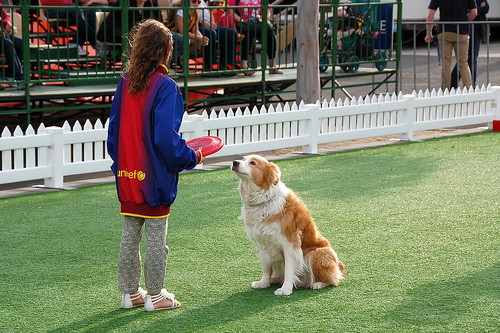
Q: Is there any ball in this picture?
A: No, there are no balls.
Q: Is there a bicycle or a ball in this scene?
A: No, there are no balls or bicycles.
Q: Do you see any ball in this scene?
A: No, there are no balls.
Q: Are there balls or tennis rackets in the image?
A: No, there are no balls or tennis rackets.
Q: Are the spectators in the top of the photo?
A: Yes, the spectators are in the top of the image.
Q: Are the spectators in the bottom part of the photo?
A: No, the spectators are in the top of the image.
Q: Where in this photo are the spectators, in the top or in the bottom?
A: The spectators are in the top of the image.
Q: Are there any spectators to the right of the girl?
A: Yes, there are spectators to the right of the girl.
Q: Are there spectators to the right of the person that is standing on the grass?
A: Yes, there are spectators to the right of the girl.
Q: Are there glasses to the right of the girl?
A: No, there are spectators to the right of the girl.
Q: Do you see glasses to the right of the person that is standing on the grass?
A: No, there are spectators to the right of the girl.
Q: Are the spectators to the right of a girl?
A: Yes, the spectators are to the right of a girl.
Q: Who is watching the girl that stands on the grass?
A: The spectators are watching the girl.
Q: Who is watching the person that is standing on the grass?
A: The spectators are watching the girl.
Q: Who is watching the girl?
A: The spectators are watching the girl.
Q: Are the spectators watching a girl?
A: Yes, the spectators are watching a girl.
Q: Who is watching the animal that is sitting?
A: The spectators are watching the dog.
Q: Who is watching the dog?
A: The spectators are watching the dog.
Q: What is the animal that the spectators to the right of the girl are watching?
A: The animal is a dog.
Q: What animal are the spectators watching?
A: The spectators are watching the dog.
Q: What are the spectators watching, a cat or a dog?
A: The spectators are watching a dog.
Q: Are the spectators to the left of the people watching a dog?
A: Yes, the spectators are watching a dog.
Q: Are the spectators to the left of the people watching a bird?
A: No, the spectators are watching a dog.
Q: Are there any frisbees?
A: Yes, there is a frisbee.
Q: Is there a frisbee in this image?
A: Yes, there is a frisbee.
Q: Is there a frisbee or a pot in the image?
A: Yes, there is a frisbee.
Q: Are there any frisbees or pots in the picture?
A: Yes, there is a frisbee.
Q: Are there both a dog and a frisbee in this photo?
A: Yes, there are both a frisbee and a dog.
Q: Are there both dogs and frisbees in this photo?
A: Yes, there are both a frisbee and a dog.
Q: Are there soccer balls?
A: No, there are no soccer balls.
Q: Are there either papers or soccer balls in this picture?
A: No, there are no soccer balls or papers.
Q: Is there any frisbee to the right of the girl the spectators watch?
A: Yes, there is a frisbee to the right of the girl.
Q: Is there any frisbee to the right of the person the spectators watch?
A: Yes, there is a frisbee to the right of the girl.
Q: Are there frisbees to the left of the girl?
A: No, the frisbee is to the right of the girl.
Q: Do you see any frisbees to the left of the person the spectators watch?
A: No, the frisbee is to the right of the girl.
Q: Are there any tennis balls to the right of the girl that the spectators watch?
A: No, there is a frisbee to the right of the girl.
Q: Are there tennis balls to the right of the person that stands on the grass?
A: No, there is a frisbee to the right of the girl.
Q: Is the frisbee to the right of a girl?
A: Yes, the frisbee is to the right of a girl.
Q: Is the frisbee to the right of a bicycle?
A: No, the frisbee is to the right of a girl.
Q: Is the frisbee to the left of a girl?
A: No, the frisbee is to the right of a girl.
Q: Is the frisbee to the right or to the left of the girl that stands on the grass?
A: The frisbee is to the right of the girl.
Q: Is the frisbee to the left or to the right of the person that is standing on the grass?
A: The frisbee is to the right of the girl.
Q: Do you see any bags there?
A: No, there are no bags.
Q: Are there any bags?
A: No, there are no bags.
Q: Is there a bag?
A: No, there are no bags.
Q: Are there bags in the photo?
A: No, there are no bags.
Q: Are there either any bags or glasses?
A: No, there are no bags or glasses.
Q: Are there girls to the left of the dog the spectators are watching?
A: Yes, there is a girl to the left of the dog.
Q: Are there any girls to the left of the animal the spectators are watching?
A: Yes, there is a girl to the left of the dog.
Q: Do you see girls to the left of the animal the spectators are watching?
A: Yes, there is a girl to the left of the dog.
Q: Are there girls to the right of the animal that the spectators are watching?
A: No, the girl is to the left of the dog.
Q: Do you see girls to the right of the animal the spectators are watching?
A: No, the girl is to the left of the dog.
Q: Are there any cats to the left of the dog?
A: No, there is a girl to the left of the dog.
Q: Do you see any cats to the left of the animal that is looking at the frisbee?
A: No, there is a girl to the left of the dog.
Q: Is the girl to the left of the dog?
A: Yes, the girl is to the left of the dog.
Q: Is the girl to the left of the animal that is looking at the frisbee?
A: Yes, the girl is to the left of the dog.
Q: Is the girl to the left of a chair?
A: No, the girl is to the left of the dog.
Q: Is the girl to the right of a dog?
A: No, the girl is to the left of a dog.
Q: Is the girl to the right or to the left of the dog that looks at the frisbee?
A: The girl is to the left of the dog.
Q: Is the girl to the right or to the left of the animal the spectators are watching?
A: The girl is to the left of the dog.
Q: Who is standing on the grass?
A: The girl is standing on the grass.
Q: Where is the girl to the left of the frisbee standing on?
A: The girl is standing on the grass.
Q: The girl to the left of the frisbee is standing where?
A: The girl is standing on the grass.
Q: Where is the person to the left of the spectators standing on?
A: The girl is standing on the grass.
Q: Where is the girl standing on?
A: The girl is standing on the grass.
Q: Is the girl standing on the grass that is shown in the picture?
A: Yes, the girl is standing on the grass.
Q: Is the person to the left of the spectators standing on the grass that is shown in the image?
A: Yes, the girl is standing on the grass.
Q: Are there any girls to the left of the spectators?
A: Yes, there is a girl to the left of the spectators.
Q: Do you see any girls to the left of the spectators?
A: Yes, there is a girl to the left of the spectators.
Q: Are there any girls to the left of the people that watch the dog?
A: Yes, there is a girl to the left of the spectators.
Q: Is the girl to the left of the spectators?
A: Yes, the girl is to the left of the spectators.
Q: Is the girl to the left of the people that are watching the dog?
A: Yes, the girl is to the left of the spectators.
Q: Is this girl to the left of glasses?
A: No, the girl is to the left of the spectators.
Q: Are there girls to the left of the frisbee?
A: Yes, there is a girl to the left of the frisbee.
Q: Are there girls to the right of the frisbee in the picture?
A: No, the girl is to the left of the frisbee.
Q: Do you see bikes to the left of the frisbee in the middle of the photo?
A: No, there is a girl to the left of the frisbee.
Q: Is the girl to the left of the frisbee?
A: Yes, the girl is to the left of the frisbee.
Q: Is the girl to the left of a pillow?
A: No, the girl is to the left of the frisbee.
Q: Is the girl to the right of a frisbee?
A: No, the girl is to the left of a frisbee.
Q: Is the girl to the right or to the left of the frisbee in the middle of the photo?
A: The girl is to the left of the frisbee.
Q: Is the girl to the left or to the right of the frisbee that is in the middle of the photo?
A: The girl is to the left of the frisbee.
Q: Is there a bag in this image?
A: No, there are no bags.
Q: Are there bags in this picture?
A: No, there are no bags.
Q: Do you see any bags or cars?
A: No, there are no bags or cars.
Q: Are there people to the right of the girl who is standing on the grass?
A: Yes, there are people to the right of the girl.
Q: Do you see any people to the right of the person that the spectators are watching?
A: Yes, there are people to the right of the girl.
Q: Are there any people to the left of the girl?
A: No, the people are to the right of the girl.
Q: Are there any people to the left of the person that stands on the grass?
A: No, the people are to the right of the girl.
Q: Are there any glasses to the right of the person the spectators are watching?
A: No, there are people to the right of the girl.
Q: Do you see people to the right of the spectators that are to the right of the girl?
A: Yes, there are people to the right of the spectators.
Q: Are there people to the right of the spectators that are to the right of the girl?
A: Yes, there are people to the right of the spectators.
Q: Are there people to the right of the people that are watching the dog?
A: Yes, there are people to the right of the spectators.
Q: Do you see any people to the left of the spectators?
A: No, the people are to the right of the spectators.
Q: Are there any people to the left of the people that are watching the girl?
A: No, the people are to the right of the spectators.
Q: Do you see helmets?
A: No, there are no helmets.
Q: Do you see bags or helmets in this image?
A: No, there are no helmets or bags.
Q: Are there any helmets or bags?
A: No, there are no helmets or bags.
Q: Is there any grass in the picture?
A: Yes, there is grass.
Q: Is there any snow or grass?
A: Yes, there is grass.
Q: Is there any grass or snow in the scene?
A: Yes, there is grass.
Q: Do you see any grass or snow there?
A: Yes, there is grass.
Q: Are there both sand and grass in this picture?
A: No, there is grass but no sand.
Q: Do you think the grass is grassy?
A: Yes, the grass is grassy.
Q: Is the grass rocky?
A: No, the grass is grassy.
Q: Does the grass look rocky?
A: No, the grass is grassy.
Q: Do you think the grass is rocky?
A: No, the grass is grassy.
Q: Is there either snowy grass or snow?
A: No, there is grass but it is grassy.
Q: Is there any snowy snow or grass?
A: No, there is grass but it is grassy.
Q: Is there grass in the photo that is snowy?
A: No, there is grass but it is grassy.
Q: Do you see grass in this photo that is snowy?
A: No, there is grass but it is grassy.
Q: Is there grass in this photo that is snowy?
A: No, there is grass but it is grassy.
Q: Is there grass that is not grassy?
A: No, there is grass but it is grassy.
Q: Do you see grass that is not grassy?
A: No, there is grass but it is grassy.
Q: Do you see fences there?
A: Yes, there is a fence.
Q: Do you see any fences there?
A: Yes, there is a fence.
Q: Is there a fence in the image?
A: Yes, there is a fence.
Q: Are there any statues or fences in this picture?
A: Yes, there is a fence.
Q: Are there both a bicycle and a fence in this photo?
A: No, there is a fence but no bicycles.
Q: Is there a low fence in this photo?
A: Yes, there is a low fence.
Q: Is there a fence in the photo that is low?
A: Yes, there is a fence that is low.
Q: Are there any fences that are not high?
A: Yes, there is a low fence.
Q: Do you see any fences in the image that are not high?
A: Yes, there is a low fence.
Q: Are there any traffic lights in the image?
A: No, there are no traffic lights.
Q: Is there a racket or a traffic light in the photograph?
A: No, there are no traffic lights or rackets.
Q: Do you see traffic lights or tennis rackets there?
A: No, there are no traffic lights or tennis rackets.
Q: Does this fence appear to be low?
A: Yes, the fence is low.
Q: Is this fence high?
A: No, the fence is low.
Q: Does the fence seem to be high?
A: No, the fence is low.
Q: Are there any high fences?
A: No, there is a fence but it is low.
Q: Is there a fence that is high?
A: No, there is a fence but it is low.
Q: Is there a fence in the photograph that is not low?
A: No, there is a fence but it is low.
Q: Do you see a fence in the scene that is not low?
A: No, there is a fence but it is low.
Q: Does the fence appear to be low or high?
A: The fence is low.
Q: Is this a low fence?
A: Yes, this is a low fence.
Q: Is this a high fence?
A: No, this is a low fence.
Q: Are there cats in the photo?
A: No, there are no cats.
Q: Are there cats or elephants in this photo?
A: No, there are no cats or elephants.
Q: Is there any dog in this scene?
A: Yes, there is a dog.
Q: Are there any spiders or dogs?
A: Yes, there is a dog.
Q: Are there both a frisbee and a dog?
A: Yes, there are both a dog and a frisbee.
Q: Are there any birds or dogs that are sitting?
A: Yes, the dog is sitting.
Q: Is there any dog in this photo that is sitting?
A: Yes, there is a dog that is sitting.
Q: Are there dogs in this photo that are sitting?
A: Yes, there is a dog that is sitting.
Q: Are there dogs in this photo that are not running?
A: Yes, there is a dog that is sitting.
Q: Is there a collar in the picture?
A: No, there are no collars.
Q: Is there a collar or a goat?
A: No, there are no collars or goats.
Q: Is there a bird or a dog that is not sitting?
A: No, there is a dog but it is sitting.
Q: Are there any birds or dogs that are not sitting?
A: No, there is a dog but it is sitting.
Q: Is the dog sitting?
A: Yes, the dog is sitting.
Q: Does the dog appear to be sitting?
A: Yes, the dog is sitting.